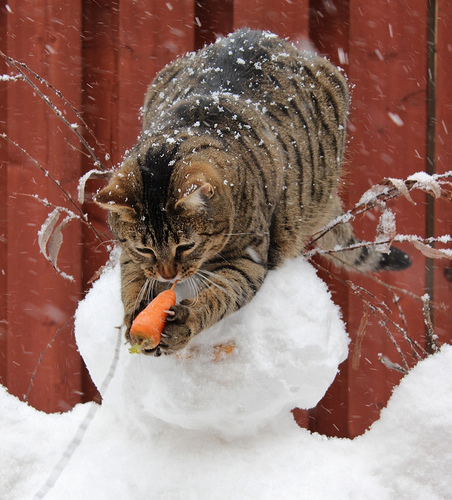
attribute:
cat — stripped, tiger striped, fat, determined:
[88, 27, 412, 360]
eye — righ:
[176, 241, 198, 262]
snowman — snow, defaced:
[2, 240, 451, 498]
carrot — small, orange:
[126, 285, 184, 357]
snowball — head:
[70, 247, 350, 438]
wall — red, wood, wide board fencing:
[1, 4, 451, 438]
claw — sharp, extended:
[159, 308, 178, 319]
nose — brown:
[162, 267, 180, 282]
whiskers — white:
[189, 267, 250, 314]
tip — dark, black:
[373, 247, 416, 272]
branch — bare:
[301, 236, 451, 264]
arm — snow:
[367, 345, 451, 497]